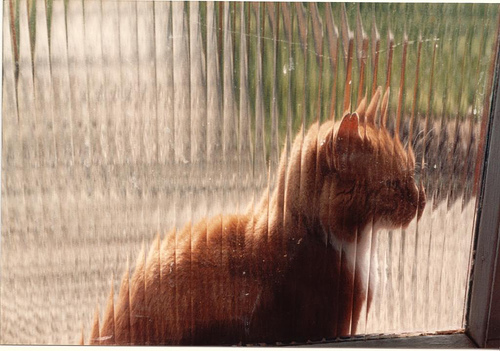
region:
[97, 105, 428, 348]
cat behind window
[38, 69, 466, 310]
window is frosted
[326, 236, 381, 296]
cat has white on front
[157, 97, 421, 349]
cat is colored tan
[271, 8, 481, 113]
outside is green grass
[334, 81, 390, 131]
reflection from glass shows ears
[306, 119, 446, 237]
cat looking to left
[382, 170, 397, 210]
eyes of cat are green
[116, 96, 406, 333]
animal is standing still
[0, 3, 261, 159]
white background in the back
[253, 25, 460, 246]
orange cat is outside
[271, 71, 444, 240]
ears are pointed up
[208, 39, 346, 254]
window is textred with lines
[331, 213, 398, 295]
cat has white under chin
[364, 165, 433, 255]
cat is facing the door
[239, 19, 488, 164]
there is green crass or trees behind the cat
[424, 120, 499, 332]
window frame is grey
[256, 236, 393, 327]
cats body is against the window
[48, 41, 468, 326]
there appears to be dirt or concrete outside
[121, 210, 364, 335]
the cat is sitting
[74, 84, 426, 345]
an orange cat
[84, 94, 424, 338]
a cat sitting outside a window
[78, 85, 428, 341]
a cat staring ahead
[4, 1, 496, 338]
a window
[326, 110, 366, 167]
the ear of the cat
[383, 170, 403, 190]
the eye of the cat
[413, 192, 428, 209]
the nose of the cat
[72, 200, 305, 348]
the body of the cat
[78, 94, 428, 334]
a cat staring through a window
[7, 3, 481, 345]
a window pane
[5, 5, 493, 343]
Cat sitting behind window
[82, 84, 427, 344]
Cat with orange and white fur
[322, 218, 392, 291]
White patch of fur under cat's chin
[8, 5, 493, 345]
Ribbed pattern in window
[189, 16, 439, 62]
Scratch on glass in window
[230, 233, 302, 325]
Dirt showing on glass in window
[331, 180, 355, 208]
Ruffled fur on side of cat's head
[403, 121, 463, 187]
Whiskers on cat's face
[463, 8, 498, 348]
Brown trim on side of window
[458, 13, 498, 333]
Brown stain bleeding onto edge of window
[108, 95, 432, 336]
the cat sitting on the other side of the door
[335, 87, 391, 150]
the ears of the car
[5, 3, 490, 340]
the glass on the door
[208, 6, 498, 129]
the grass in the yard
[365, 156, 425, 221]
the serious face of the cat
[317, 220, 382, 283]
the white fur of the cat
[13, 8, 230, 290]
a sidewalk next to the yard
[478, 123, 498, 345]
some of the wood on the door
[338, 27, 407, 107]
a reflection of the ears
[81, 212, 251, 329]
the back of the kitty